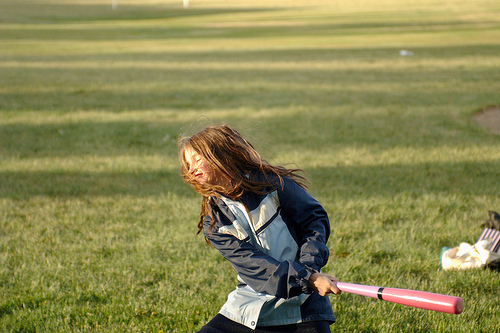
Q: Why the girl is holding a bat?
A: To play.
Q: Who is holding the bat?
A: The girl.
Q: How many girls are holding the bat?
A: One.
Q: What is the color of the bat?
A: Pink.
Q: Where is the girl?
A: In the park.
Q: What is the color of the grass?
A: Green.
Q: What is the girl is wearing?
A: Jacket.